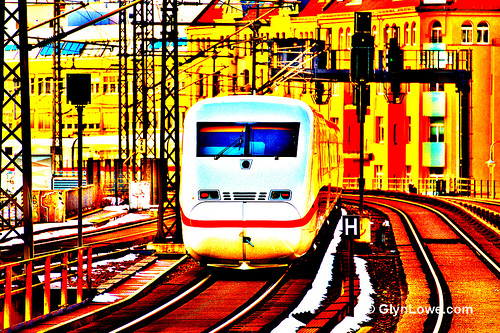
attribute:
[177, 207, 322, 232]
line — red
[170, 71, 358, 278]
train — white, yellow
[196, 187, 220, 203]
light — red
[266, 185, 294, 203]
light — red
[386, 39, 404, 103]
traffic light — green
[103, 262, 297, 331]
track — white, black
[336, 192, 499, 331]
track — black, white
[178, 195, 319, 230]
stripe — red